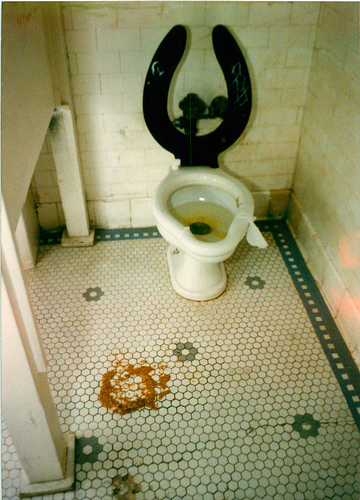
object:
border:
[36, 218, 358, 499]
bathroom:
[1, 1, 358, 499]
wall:
[55, 2, 327, 251]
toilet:
[141, 24, 254, 302]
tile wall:
[285, 1, 360, 370]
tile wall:
[30, 2, 319, 229]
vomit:
[97, 351, 175, 419]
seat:
[142, 24, 253, 168]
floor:
[20, 227, 360, 499]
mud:
[98, 352, 171, 415]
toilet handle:
[171, 115, 184, 129]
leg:
[48, 103, 90, 238]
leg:
[1, 258, 69, 485]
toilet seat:
[141, 24, 253, 169]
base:
[284, 186, 359, 362]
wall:
[280, 1, 359, 361]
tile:
[273, 217, 342, 317]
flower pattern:
[242, 274, 267, 290]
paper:
[245, 213, 269, 249]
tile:
[221, 309, 326, 422]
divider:
[1, 1, 97, 496]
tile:
[173, 341, 198, 363]